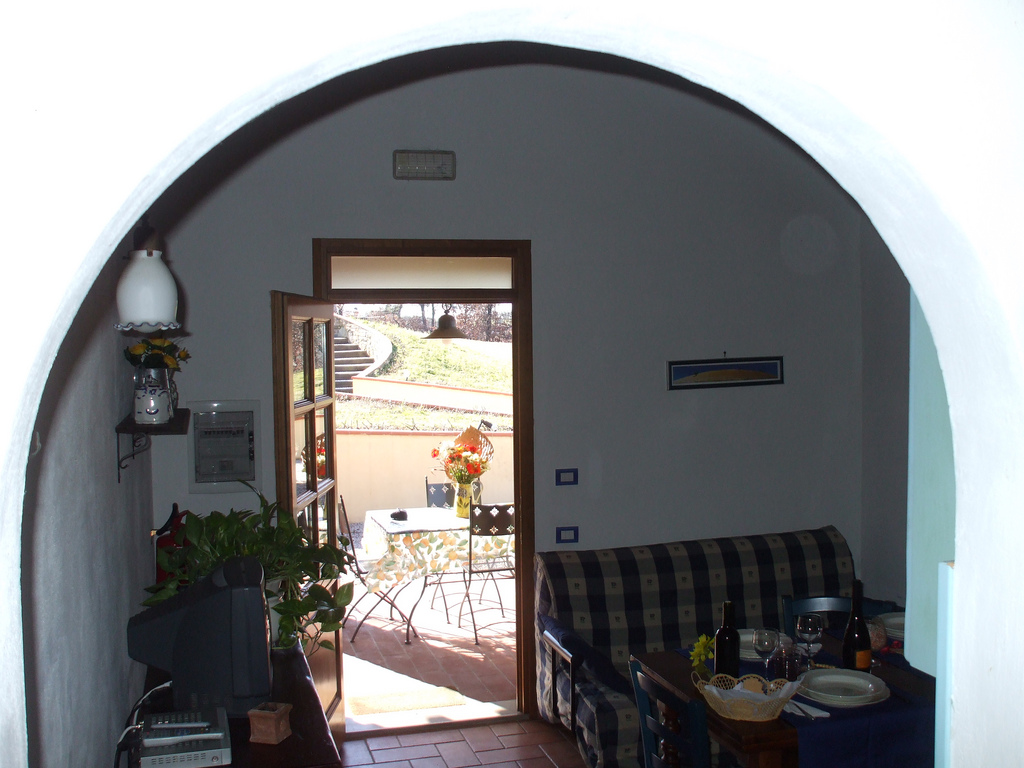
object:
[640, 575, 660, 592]
square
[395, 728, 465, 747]
bricks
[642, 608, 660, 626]
square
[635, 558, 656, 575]
square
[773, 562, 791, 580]
square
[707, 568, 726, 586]
square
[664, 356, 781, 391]
framed picture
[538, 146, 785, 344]
wall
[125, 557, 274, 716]
television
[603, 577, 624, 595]
square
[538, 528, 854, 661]
cover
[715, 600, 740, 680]
bottle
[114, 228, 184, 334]
lamp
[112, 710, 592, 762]
floor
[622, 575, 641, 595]
square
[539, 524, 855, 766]
couch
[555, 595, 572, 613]
square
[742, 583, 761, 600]
square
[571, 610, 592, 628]
square